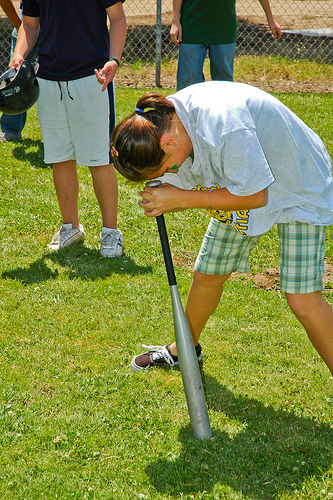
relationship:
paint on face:
[170, 164, 178, 171] [141, 155, 186, 178]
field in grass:
[7, 208, 269, 497] [7, 290, 127, 498]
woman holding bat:
[108, 76, 333, 380] [145, 177, 216, 443]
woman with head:
[105, 79, 321, 371] [97, 92, 203, 194]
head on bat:
[97, 92, 203, 194] [137, 176, 219, 436]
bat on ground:
[145, 177, 216, 443] [0, 87, 333, 496]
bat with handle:
[126, 181, 227, 442] [148, 215, 177, 286]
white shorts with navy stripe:
[33, 79, 131, 176] [100, 84, 120, 120]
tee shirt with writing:
[148, 81, 332, 236] [181, 178, 252, 239]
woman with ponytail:
[108, 76, 333, 380] [135, 93, 174, 114]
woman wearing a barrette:
[108, 76, 333, 380] [107, 143, 120, 156]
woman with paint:
[105, 79, 321, 371] [168, 161, 177, 171]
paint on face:
[168, 161, 177, 171] [131, 131, 200, 187]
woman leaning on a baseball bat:
[105, 79, 321, 371] [144, 182, 214, 437]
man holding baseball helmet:
[8, 0, 130, 262] [0, 57, 39, 113]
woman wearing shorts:
[108, 76, 333, 380] [193, 219, 328, 296]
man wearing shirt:
[161, 1, 279, 79] [178, 9, 238, 46]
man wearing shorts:
[8, 0, 130, 262] [32, 72, 115, 164]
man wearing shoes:
[29, 14, 128, 233] [38, 192, 145, 263]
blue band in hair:
[132, 103, 147, 115] [103, 89, 180, 184]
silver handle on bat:
[144, 181, 162, 187] [145, 177, 216, 443]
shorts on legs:
[190, 212, 331, 291] [164, 247, 331, 383]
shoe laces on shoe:
[136, 333, 192, 372] [130, 338, 205, 371]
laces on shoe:
[98, 227, 121, 248] [97, 221, 123, 260]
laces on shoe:
[48, 221, 74, 247] [48, 220, 86, 253]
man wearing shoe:
[8, 0, 130, 262] [48, 218, 83, 251]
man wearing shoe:
[8, 0, 130, 262] [95, 229, 124, 256]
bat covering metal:
[145, 177, 216, 443] [170, 283, 211, 440]